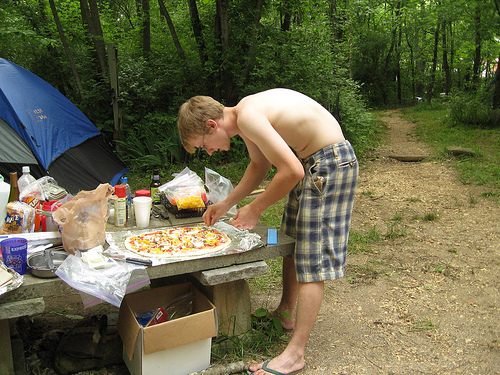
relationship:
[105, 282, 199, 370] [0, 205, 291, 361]
box under table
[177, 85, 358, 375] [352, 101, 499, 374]
man close to path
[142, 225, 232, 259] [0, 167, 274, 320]
pizza walking on table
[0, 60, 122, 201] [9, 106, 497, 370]
tent on ground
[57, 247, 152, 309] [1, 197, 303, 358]
bags are on table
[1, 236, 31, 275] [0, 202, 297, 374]
cup on table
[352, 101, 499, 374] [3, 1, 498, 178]
path in woods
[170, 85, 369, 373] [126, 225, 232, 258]
man making pizza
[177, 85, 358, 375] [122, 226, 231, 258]
man getting some pizza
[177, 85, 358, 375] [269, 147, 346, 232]
man wearing short pants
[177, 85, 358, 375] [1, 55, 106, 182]
man close to a tent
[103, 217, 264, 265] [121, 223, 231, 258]
aluminum foil under pizza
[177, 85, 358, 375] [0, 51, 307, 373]
man has set up a campsite